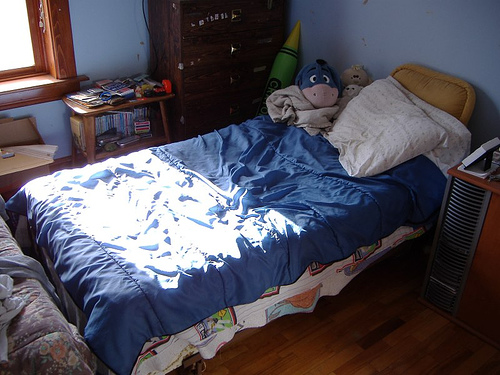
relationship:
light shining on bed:
[32, 192, 252, 303] [319, 197, 357, 267]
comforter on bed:
[3, 109, 447, 374] [341, 193, 369, 231]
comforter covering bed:
[3, 109, 447, 374] [0, 75, 450, 371]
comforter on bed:
[3, 109, 447, 374] [0, 75, 450, 371]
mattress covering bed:
[26, 113, 428, 299] [21, 64, 445, 350]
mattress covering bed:
[26, 113, 428, 299] [3, 60, 473, 371]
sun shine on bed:
[20, 147, 309, 297] [3, 60, 473, 371]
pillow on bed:
[323, 76, 440, 179] [0, 107, 454, 370]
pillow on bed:
[382, 71, 470, 173] [0, 107, 454, 370]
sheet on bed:
[132, 220, 426, 372] [3, 60, 473, 371]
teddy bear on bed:
[335, 60, 378, 94] [3, 60, 473, 371]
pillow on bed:
[321, 78, 451, 180] [3, 60, 473, 371]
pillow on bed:
[382, 71, 470, 173] [3, 60, 473, 371]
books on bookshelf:
[89, 100, 161, 144] [67, 74, 177, 166]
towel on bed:
[260, 79, 344, 141] [3, 60, 473, 371]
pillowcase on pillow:
[323, 74, 449, 178] [323, 76, 440, 179]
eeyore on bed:
[294, 56, 340, 109] [0, 107, 454, 370]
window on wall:
[2, 2, 52, 80] [0, 2, 150, 158]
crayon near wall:
[265, 20, 303, 90] [286, 2, 498, 132]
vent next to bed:
[421, 167, 490, 293] [0, 107, 454, 370]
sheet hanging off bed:
[132, 220, 426, 372] [0, 107, 454, 370]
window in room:
[0, 0, 45, 80] [0, 0, 498, 370]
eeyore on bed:
[294, 53, 344, 113] [0, 107, 454, 370]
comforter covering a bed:
[3, 109, 447, 374] [3, 60, 473, 371]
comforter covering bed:
[80, 188, 190, 288] [24, 97, 471, 373]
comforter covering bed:
[3, 109, 447, 374] [0, 107, 454, 370]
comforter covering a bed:
[3, 109, 447, 374] [0, 75, 450, 371]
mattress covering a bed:
[26, 113, 428, 299] [24, 97, 471, 373]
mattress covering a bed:
[26, 113, 428, 299] [0, 107, 454, 370]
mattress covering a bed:
[216, 123, 315, 258] [24, 97, 471, 373]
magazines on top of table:
[70, 77, 150, 105] [63, 73, 174, 159]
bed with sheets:
[0, 107, 454, 370] [22, 138, 390, 319]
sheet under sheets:
[133, 228, 427, 375] [129, 227, 449, 362]